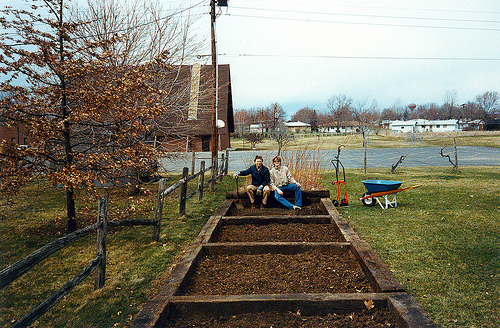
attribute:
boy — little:
[267, 154, 307, 213]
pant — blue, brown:
[271, 179, 318, 211]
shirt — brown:
[270, 164, 296, 183]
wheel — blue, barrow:
[349, 184, 394, 213]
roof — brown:
[134, 73, 224, 139]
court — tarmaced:
[175, 205, 347, 326]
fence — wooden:
[109, 169, 221, 271]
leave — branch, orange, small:
[112, 62, 172, 140]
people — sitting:
[223, 146, 314, 210]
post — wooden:
[180, 24, 249, 175]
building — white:
[382, 101, 480, 145]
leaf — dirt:
[356, 298, 380, 324]